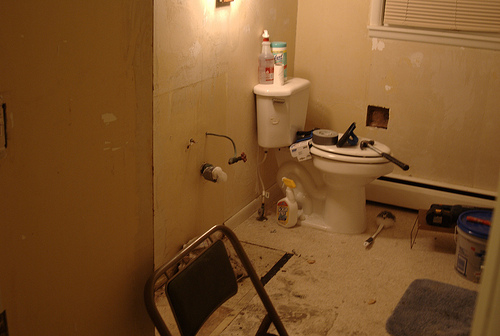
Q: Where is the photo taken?
A: Bathroom.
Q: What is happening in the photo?
A: Remodeling.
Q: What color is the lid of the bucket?
A: Blue.